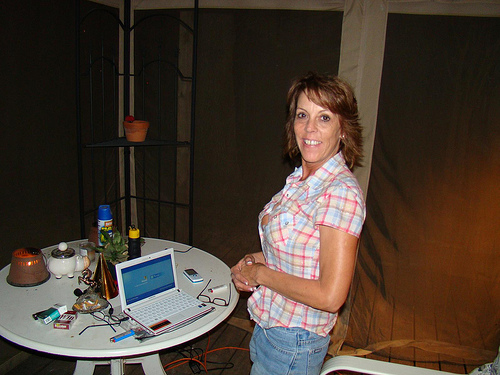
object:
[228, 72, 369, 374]
woman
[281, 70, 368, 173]
hair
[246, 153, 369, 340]
shirt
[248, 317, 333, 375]
jeans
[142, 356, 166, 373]
leg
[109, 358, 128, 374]
leg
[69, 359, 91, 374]
leg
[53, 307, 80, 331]
cigarette pack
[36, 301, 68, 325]
cigarette pack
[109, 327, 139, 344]
blue lighter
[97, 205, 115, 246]
can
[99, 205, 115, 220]
top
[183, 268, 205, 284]
cellphone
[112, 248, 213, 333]
computer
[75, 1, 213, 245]
stand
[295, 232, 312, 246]
pattern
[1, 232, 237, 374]
white table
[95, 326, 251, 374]
floor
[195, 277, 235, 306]
glasses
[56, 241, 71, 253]
candle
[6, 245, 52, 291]
candle holder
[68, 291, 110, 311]
ashtray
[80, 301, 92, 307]
butts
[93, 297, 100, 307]
butts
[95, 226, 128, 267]
items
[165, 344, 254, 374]
electrical cords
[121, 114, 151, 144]
clay pot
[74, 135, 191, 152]
shelf